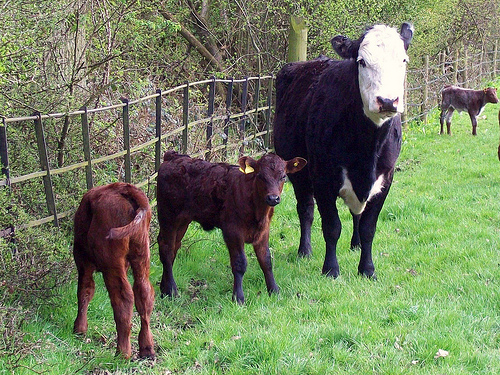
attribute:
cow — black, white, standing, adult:
[260, 18, 417, 286]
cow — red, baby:
[63, 181, 161, 363]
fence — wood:
[0, 35, 498, 295]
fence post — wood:
[281, 15, 311, 65]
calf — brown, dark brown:
[150, 151, 310, 307]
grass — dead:
[178, 277, 212, 303]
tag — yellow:
[243, 163, 257, 176]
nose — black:
[263, 194, 282, 206]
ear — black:
[329, 34, 359, 61]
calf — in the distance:
[436, 80, 499, 136]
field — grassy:
[0, 77, 499, 375]